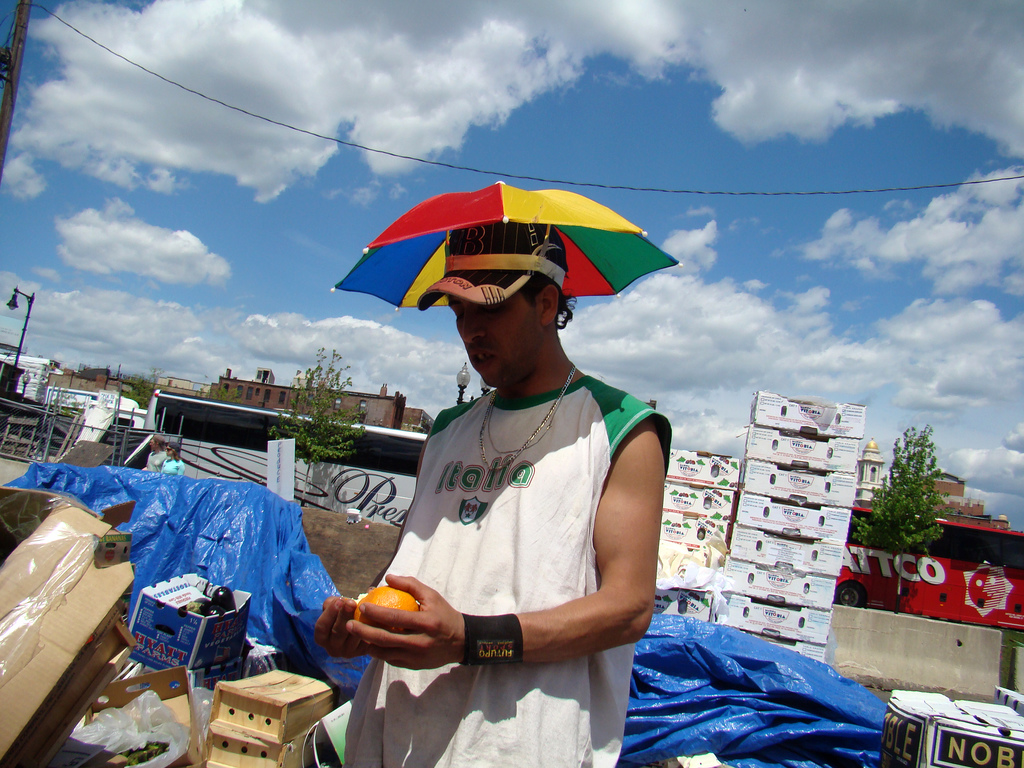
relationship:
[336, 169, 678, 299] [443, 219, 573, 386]
umbrella on head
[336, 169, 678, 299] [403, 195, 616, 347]
umbrella on man's hat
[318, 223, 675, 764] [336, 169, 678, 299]
man wearing umbrella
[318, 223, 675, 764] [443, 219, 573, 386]
man has head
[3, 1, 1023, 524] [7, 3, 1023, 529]
clouds in sky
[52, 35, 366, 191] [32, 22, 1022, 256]
clouds in sky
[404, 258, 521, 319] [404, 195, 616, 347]
bill of man's hat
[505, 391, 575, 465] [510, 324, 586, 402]
necklace around neck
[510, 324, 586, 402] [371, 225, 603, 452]
neck of man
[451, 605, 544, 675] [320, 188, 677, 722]
wristband on man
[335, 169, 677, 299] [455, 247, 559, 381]
umbrella worn by man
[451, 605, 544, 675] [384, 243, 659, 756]
wristband worn by man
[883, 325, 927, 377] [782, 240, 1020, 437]
clouds in sky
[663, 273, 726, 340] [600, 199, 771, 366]
clouds in sky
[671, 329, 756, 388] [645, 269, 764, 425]
clouds in sky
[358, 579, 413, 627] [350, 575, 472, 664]
orange in hand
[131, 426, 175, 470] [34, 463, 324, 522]
people walking behind tarp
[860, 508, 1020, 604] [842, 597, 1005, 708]
bus behind barriers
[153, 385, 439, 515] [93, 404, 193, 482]
bus behind people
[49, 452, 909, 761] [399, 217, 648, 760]
tarps behind man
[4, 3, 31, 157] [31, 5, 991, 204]
pole with wire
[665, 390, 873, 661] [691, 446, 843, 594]
pile of boxes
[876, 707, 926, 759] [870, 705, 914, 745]
signing with letters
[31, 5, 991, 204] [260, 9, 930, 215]
wire streaming across sky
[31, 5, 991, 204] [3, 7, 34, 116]
wire from a pole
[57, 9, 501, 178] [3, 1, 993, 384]
clouds in a sky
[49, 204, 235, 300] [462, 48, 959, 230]
clouds in sky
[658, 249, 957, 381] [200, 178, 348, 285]
clouds in sky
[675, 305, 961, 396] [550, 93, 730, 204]
clouds in sky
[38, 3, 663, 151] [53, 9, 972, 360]
clouds in sky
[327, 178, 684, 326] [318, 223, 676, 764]
hat on man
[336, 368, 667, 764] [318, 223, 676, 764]
top on man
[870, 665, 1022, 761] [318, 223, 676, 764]
box behind man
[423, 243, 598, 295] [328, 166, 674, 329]
strap for hat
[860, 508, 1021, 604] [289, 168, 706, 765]
bus behind man